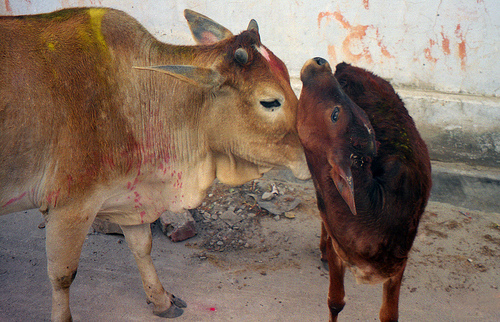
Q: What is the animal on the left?
A: Cow.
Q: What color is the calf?
A: Dark brown.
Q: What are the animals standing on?
A: Dirt.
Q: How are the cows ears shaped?
A: Pointy.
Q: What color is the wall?
A: White.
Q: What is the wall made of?
A: Brick.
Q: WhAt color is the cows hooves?
A: Black.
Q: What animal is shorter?
A: The one without the spots.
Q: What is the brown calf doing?
A: Looking up.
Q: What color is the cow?
A: Light brown.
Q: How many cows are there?
A: Two.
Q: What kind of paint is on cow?
A: Yellow.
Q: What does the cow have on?
A: Red paint.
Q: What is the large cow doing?
A: Nuzzling the smaller one.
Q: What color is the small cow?
A: Dark.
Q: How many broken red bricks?
A: Two.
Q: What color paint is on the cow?
A: Yellow.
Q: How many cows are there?
A: 2.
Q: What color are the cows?
A: Brown.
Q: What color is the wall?
A: White.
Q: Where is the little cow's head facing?
A: Upwards.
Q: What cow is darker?
A: The small cow.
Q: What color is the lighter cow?
A: Tan.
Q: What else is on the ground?
A: Gravel.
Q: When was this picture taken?
A: The daytime.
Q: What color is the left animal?
A: Dark brown.